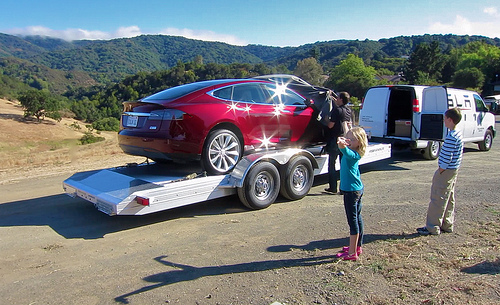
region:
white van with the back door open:
[355, 74, 492, 155]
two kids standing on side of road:
[315, 98, 466, 243]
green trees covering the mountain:
[22, 25, 467, 92]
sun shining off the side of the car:
[226, 71, 292, 153]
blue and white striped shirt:
[430, 125, 469, 175]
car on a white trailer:
[111, 51, 390, 211]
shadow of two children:
[109, 220, 445, 300]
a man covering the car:
[260, 64, 373, 195]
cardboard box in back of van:
[388, 114, 416, 144]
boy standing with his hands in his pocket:
[423, 105, 470, 246]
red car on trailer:
[105, 75, 325, 186]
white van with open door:
[362, 82, 492, 148]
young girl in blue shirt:
[330, 125, 365, 265]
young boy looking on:
[415, 100, 457, 245]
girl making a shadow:
[100, 231, 335, 297]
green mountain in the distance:
[0, 0, 165, 130]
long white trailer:
[55, 155, 315, 220]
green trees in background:
[420, 35, 495, 85]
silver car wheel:
[196, 105, 242, 180]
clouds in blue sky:
[1, 2, 496, 47]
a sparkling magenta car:
[136, 74, 317, 154]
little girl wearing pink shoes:
[334, 242, 364, 262]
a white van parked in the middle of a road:
[363, 77, 493, 142]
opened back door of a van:
[405, 80, 445, 131]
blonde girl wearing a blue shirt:
[335, 120, 374, 192]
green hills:
[26, 27, 478, 69]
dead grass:
[389, 232, 496, 302]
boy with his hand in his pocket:
[429, 152, 466, 189]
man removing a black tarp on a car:
[315, 80, 356, 125]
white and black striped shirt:
[434, 125, 471, 166]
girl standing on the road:
[337, 126, 365, 261]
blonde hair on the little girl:
[350, 125, 369, 155]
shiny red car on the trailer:
[119, 81, 327, 159]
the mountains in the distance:
[12, 33, 465, 83]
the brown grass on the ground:
[1, 116, 74, 174]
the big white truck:
[363, 83, 494, 154]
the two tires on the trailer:
[241, 161, 313, 201]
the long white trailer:
[54, 145, 391, 212]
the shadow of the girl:
[115, 249, 353, 301]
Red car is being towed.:
[67, 45, 482, 220]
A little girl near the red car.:
[315, 120, 375, 285]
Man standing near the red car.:
[322, 86, 357, 196]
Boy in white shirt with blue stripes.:
[400, 92, 482, 242]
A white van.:
[357, 65, 487, 152]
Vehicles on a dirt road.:
[0, 65, 492, 295]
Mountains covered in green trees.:
[0, 25, 470, 105]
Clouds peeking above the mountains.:
[11, 15, 346, 55]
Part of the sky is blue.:
[71, 5, 346, 20]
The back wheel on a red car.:
[195, 121, 242, 172]